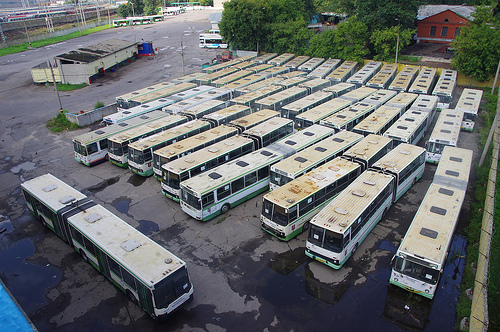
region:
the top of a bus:
[56, 196, 209, 296]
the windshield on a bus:
[139, 268, 216, 323]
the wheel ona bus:
[206, 196, 240, 221]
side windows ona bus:
[205, 168, 258, 210]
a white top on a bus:
[59, 200, 179, 279]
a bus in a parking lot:
[64, 150, 229, 321]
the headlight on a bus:
[251, 214, 308, 254]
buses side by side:
[245, 132, 418, 236]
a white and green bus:
[173, 140, 295, 234]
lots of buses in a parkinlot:
[108, 55, 462, 230]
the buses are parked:
[51, 33, 474, 317]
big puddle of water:
[238, 240, 439, 328]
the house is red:
[418, 10, 475, 50]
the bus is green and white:
[159, 137, 301, 244]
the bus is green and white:
[164, 123, 354, 293]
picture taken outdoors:
[7, 5, 498, 325]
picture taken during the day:
[7, 8, 479, 325]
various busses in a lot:
[8, 6, 480, 308]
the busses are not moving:
[21, 59, 389, 329]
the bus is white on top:
[82, 210, 167, 278]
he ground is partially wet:
[254, 260, 356, 318]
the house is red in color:
[415, 6, 465, 48]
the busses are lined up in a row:
[118, 80, 445, 291]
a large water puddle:
[271, 288, 395, 326]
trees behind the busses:
[227, 6, 401, 57]